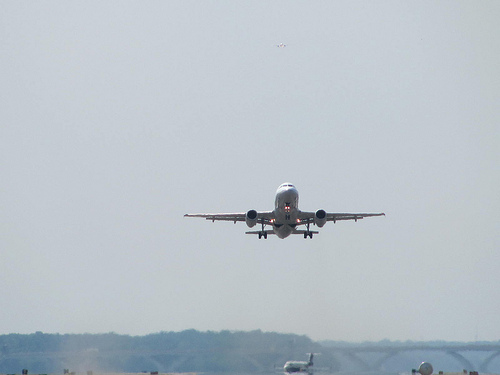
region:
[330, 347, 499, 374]
A bridge in the distance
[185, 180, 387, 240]
An airplane in the air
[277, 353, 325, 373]
An airplane on the runway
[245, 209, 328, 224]
Engines on the airplane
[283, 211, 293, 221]
Wheels on the airplane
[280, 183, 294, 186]
Windows on the front of the airplane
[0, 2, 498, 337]
The sky above the airplanes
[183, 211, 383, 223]
The wings of the airplane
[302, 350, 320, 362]
The tail of the airplane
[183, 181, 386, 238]
The airplane is taking off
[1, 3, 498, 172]
clear sky with no clouds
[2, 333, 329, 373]
distant growth of trees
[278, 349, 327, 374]
plane on land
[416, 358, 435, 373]
spherical ball on ground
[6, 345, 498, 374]
distant bridge for travel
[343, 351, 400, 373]
cross structures for bridge support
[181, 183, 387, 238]
airplane in the sky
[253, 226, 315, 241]
wheels for landing or take off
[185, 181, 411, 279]
a jet plane is landing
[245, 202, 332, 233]
the jet engines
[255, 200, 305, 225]
the plane has it's landing lights on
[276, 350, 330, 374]
another plane waits on the runway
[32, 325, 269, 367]
lots of trees in the background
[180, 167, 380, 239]
the plane is white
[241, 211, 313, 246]
the landing gear is down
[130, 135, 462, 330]
it appears to be an overcast day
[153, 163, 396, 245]
the plane has it's wing flaps down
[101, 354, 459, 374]
airplanes still on the ground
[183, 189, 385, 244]
a plane that is taking off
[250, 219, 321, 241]
lowered landing gear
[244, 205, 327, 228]
two engines, one on each wing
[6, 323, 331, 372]
hill in the distance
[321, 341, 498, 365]
a bridge spanning a gorge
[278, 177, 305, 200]
cockpit and nose of the plane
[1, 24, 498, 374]
sky is grey and hazy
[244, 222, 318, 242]
rear wings of a plane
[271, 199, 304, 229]
lights lit on the underside of the plane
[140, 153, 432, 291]
the airplane is flying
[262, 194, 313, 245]
the lights are on the plane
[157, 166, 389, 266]
the plane is white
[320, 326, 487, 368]
a bridge in the distance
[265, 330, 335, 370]
a plane is getting ready for take off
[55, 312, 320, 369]
the trees are in the background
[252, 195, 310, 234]
the lights are white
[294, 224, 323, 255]
the wheels are black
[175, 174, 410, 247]
Airplane flying in the sky.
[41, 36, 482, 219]
The sky is overcast.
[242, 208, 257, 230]
Engine on the plane.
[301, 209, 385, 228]
wing belongs to plane